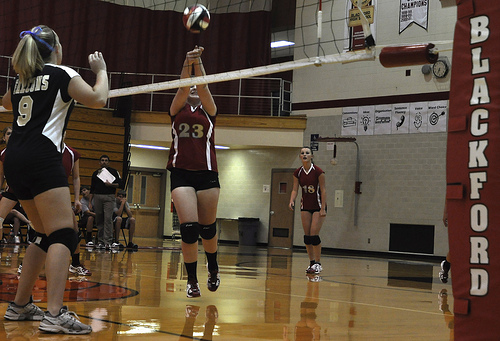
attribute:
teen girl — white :
[3, 21, 108, 334]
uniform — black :
[2, 63, 82, 201]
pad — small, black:
[43, 225, 78, 255]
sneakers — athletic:
[156, 270, 223, 307]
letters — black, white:
[466, 14, 491, 299]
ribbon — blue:
[16, 27, 46, 42]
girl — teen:
[288, 141, 345, 276]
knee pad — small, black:
[308, 231, 322, 247]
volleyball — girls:
[6, 5, 489, 340]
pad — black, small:
[178, 227, 220, 244]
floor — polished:
[1, 236, 492, 339]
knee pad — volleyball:
[177, 218, 202, 248]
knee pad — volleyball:
[196, 217, 220, 242]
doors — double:
[122, 164, 174, 234]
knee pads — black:
[171, 215, 230, 247]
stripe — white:
[197, 120, 218, 169]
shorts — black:
[299, 191, 321, 215]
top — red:
[283, 168, 325, 206]